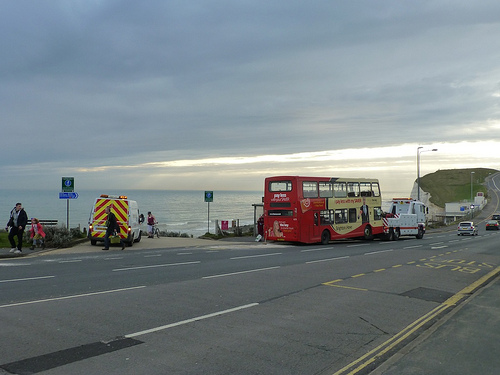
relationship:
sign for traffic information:
[56, 174, 82, 203] [63, 176, 76, 198]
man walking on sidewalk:
[3, 200, 29, 256] [0, 243, 52, 259]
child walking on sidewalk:
[25, 215, 49, 254] [0, 243, 52, 259]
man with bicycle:
[144, 209, 157, 240] [151, 224, 164, 243]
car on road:
[452, 217, 482, 240] [0, 165, 499, 373]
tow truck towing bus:
[381, 191, 434, 244] [255, 170, 390, 252]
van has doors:
[83, 190, 148, 251] [93, 199, 130, 241]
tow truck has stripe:
[381, 191, 434, 244] [386, 220, 421, 234]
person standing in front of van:
[144, 209, 157, 240] [83, 190, 148, 251]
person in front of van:
[144, 209, 157, 240] [83, 190, 148, 251]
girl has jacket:
[25, 215, 49, 254] [24, 220, 50, 243]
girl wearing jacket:
[25, 215, 49, 254] [24, 220, 50, 243]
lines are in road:
[312, 247, 497, 375] [0, 165, 499, 373]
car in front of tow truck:
[452, 217, 482, 240] [381, 191, 434, 244]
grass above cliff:
[415, 156, 500, 210] [407, 165, 499, 225]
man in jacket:
[3, 200, 29, 256] [3, 206, 31, 230]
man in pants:
[3, 200, 29, 256] [5, 225, 27, 253]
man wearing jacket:
[3, 200, 29, 256] [3, 206, 31, 230]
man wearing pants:
[3, 200, 29, 256] [5, 225, 27, 253]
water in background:
[2, 188, 393, 237] [0, 0, 499, 237]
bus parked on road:
[255, 170, 390, 252] [0, 165, 499, 373]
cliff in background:
[407, 165, 499, 225] [0, 0, 499, 237]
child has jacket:
[25, 215, 49, 254] [24, 220, 50, 243]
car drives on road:
[452, 217, 482, 240] [0, 165, 499, 373]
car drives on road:
[486, 218, 500, 233] [0, 165, 499, 373]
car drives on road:
[490, 209, 500, 221] [0, 165, 499, 373]